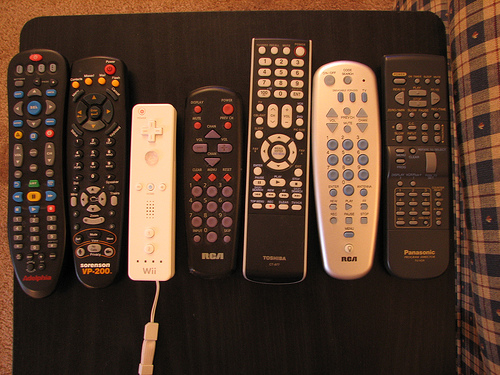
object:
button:
[395, 87, 407, 108]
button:
[405, 85, 430, 97]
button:
[405, 98, 430, 110]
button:
[427, 90, 442, 107]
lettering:
[132, 255, 160, 274]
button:
[190, 185, 202, 198]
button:
[190, 199, 203, 212]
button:
[191, 215, 202, 228]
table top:
[11, 12, 458, 373]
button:
[326, 139, 340, 153]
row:
[189, 170, 234, 182]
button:
[191, 172, 201, 182]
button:
[205, 172, 216, 182]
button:
[221, 170, 231, 182]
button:
[325, 106, 340, 121]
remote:
[305, 55, 381, 281]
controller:
[65, 48, 133, 296]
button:
[434, 190, 444, 197]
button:
[356, 136, 371, 149]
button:
[356, 167, 370, 182]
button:
[323, 166, 338, 182]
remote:
[68, 52, 121, 286]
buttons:
[219, 36, 386, 229]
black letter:
[340, 256, 346, 263]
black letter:
[347, 256, 352, 262]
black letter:
[352, 256, 359, 261]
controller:
[310, 63, 380, 279]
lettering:
[18, 273, 53, 280]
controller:
[4, 47, 70, 301]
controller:
[378, 52, 453, 284]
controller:
[125, 100, 177, 285]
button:
[395, 192, 405, 197]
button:
[288, 65, 313, 77]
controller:
[244, 29, 319, 283]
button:
[355, 137, 369, 155]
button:
[424, 148, 437, 174]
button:
[83, 184, 105, 199]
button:
[86, 243, 102, 253]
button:
[266, 103, 279, 130]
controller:
[178, 83, 242, 283]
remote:
[379, 42, 453, 284]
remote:
[186, 82, 244, 284]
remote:
[236, 38, 316, 289]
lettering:
[401, 248, 436, 257]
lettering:
[262, 251, 285, 261]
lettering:
[201, 250, 222, 260]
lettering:
[80, 262, 109, 266]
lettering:
[28, 55, 40, 61]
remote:
[381, 52, 451, 279]